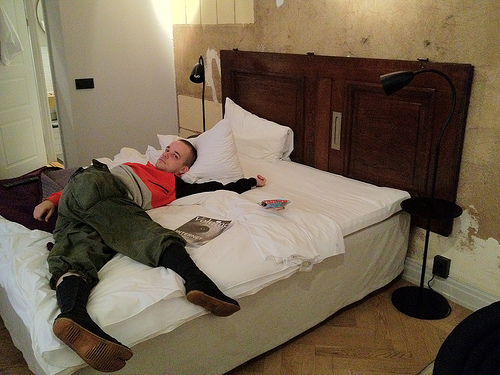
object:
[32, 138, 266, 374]
man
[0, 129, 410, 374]
bed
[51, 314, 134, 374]
sole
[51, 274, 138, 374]
left shoe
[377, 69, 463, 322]
lamp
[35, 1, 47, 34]
mirror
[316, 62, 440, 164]
headboard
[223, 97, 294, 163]
pillow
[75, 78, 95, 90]
switch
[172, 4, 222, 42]
wall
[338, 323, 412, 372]
floor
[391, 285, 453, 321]
base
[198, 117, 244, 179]
pillow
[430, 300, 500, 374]
table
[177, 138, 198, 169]
hair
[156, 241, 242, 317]
right shoe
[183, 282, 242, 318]
foot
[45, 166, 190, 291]
pants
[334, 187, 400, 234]
matress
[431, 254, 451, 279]
plug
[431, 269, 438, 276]
outlet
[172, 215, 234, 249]
magazine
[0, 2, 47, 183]
door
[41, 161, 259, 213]
shirt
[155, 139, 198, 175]
head